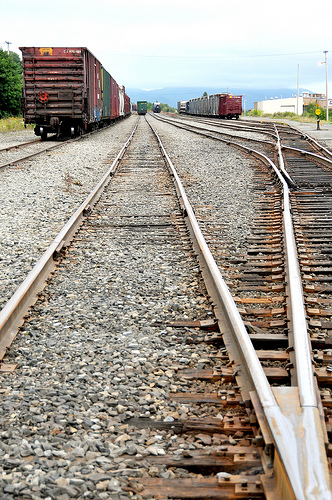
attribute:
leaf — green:
[4, 75, 16, 81]